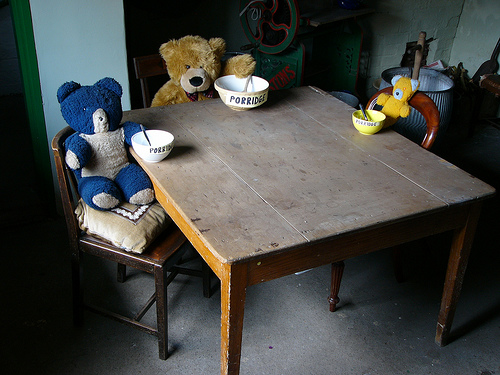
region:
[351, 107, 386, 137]
yellow bowl with white trim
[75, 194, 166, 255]
light brown throw pillow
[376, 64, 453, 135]
silver metal garbage can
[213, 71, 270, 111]
tan bowl that says porridge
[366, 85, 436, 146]
shiny brown wooden chair top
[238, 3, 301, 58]
green wheel with red trim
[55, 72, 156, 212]
blue and white bear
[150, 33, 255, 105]
light brown teddy bear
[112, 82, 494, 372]
worn wooden dining table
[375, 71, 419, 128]
tiny yellow teddy bear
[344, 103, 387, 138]
a yellow bowl on the table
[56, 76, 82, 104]
a blue teddy bear ear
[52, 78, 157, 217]
a blue and white teddy bear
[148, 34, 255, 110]
a brown teddy bear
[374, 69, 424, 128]
a yellow and white teddy bear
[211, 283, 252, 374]
the leg of a table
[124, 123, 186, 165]
a white bowl on the table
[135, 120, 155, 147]
a gray metal eating utensil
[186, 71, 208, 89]
the nose of a teddy bear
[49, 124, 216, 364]
a brown wooden chair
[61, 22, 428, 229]
three teddy bears around table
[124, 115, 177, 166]
white bowl and utensil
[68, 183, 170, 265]
pillow on wood chair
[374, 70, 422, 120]
yellow bear with white ears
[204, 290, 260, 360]
leg of wood table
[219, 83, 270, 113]
word on side of bowl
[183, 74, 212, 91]
black nose on bear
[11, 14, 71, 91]
green door frame and white wall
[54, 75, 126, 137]
blue and white bear head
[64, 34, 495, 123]
the three bears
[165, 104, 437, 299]
old wooden table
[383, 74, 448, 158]
yellow colored bear doll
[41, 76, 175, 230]
blue and white colored toy bear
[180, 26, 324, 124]
light brown colored bear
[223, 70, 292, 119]
bowl with porridge label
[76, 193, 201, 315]
seat cushion on chair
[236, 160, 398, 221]
weathered table top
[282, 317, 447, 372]
bare flooring grey colored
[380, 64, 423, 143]
small sized bear doll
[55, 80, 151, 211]
Stuffed teddy bear sitting on a chair.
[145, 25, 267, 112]
Stuffed teddy bear holding spoon.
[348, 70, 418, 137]
Small stuffed teddy bear sitting.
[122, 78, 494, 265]
Top of a wooden table.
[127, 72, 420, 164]
Three bowls on a wooden table.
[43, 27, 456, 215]
Three stuffed teddy bears sitting.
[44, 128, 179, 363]
Wooden chair with stuffed teddy bears sitting on it.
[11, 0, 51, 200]
Green door frame behind the teddy bears.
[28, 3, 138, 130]
Light blue painted wall in the room.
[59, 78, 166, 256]
Blue and white teddy bear sitting on pillow.